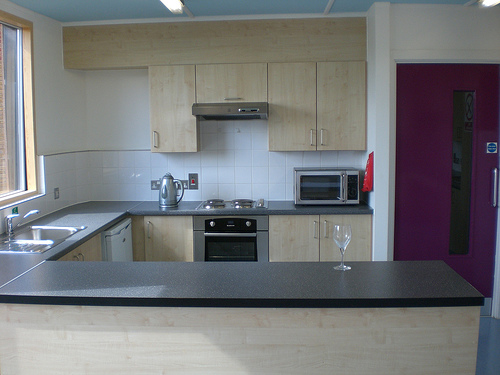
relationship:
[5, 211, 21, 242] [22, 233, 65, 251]
tap on sink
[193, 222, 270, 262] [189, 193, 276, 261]
oven under stove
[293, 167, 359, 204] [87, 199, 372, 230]
black microwave on counter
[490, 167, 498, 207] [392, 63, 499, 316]
door handle on door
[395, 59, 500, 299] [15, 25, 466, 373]
door next to kitchen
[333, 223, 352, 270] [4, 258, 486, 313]
glass on counter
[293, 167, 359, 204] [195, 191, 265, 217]
black microwave next to stove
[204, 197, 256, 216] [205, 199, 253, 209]
burners on burners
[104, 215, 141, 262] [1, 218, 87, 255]
dishwasher next to sink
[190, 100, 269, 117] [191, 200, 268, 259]
hood vent above stove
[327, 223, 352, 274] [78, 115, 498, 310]
glass on a counter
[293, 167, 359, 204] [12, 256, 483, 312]
black microwave on a countertop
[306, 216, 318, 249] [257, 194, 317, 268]
handle on cabinet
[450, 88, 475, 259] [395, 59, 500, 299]
window on door